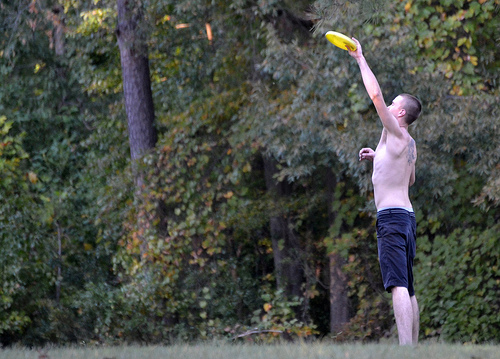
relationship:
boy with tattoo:
[326, 44, 430, 309] [399, 136, 419, 174]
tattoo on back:
[399, 136, 419, 174] [385, 128, 415, 209]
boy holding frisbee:
[326, 44, 430, 309] [314, 23, 371, 67]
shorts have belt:
[377, 203, 424, 297] [373, 203, 423, 221]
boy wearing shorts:
[326, 44, 430, 309] [377, 203, 424, 297]